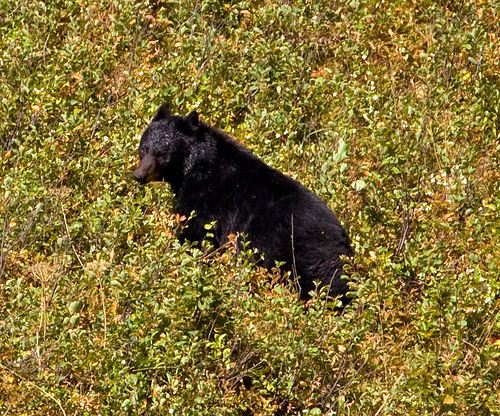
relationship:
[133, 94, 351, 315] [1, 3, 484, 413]
bear in field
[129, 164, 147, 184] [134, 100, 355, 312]
black nose of dog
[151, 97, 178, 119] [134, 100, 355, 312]
ear of dog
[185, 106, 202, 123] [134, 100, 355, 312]
ear of dog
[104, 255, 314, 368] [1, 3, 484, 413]
grass in field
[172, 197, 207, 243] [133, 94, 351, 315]
legs of bear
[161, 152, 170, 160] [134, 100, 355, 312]
left eye of dog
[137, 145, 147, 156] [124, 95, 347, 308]
eye of dog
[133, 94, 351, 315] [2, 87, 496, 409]
bear surrounded by shrubs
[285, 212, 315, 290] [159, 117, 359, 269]
twig in front of bear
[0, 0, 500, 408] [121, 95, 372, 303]
shrubs engulfing bear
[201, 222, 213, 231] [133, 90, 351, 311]
leaf in front of bear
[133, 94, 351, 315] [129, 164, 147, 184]
bear has long black nose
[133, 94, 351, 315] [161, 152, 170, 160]
bear has left eye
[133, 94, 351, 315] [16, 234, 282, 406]
bear sitting in trees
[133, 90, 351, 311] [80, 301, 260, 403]
bear sitting in trees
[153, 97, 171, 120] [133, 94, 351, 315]
ear of bear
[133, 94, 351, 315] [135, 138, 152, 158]
bear has eye